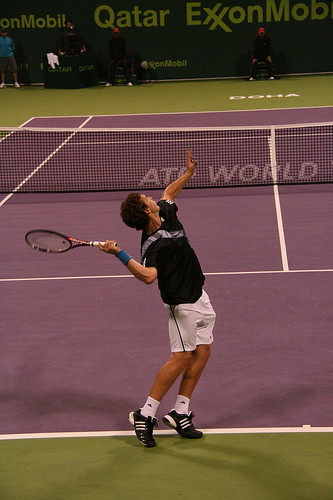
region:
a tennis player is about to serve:
[30, 154, 261, 408]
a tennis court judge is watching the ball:
[244, 24, 283, 86]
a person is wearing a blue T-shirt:
[0, 19, 32, 88]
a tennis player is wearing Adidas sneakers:
[127, 401, 204, 452]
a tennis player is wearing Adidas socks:
[124, 385, 205, 414]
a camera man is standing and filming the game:
[57, 17, 86, 65]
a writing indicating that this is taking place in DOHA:
[218, 91, 316, 106]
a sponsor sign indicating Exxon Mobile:
[180, 0, 332, 36]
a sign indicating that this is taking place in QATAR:
[42, 66, 85, 79]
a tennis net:
[2, 121, 331, 192]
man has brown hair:
[120, 195, 152, 232]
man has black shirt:
[122, 221, 198, 306]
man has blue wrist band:
[110, 246, 139, 275]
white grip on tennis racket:
[75, 233, 116, 264]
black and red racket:
[20, 224, 88, 252]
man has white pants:
[158, 304, 211, 340]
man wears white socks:
[120, 388, 180, 425]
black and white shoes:
[120, 404, 169, 463]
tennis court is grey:
[61, 188, 307, 435]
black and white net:
[15, 121, 248, 194]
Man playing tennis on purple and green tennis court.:
[17, 143, 251, 449]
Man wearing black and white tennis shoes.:
[123, 405, 209, 449]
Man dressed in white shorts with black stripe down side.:
[151, 285, 216, 358]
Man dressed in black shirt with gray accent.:
[133, 197, 216, 308]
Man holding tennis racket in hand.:
[22, 223, 118, 254]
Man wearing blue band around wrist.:
[113, 244, 137, 270]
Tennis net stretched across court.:
[115, 120, 332, 192]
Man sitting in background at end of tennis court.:
[248, 24, 287, 89]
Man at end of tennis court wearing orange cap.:
[252, 25, 269, 38]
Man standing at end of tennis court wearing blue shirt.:
[1, 36, 22, 67]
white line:
[239, 418, 304, 452]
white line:
[234, 410, 286, 446]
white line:
[247, 385, 309, 483]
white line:
[228, 415, 292, 476]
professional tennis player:
[76, 157, 244, 475]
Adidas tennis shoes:
[116, 406, 161, 450]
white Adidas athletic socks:
[138, 390, 159, 422]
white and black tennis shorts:
[151, 295, 216, 345]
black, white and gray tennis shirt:
[115, 197, 205, 304]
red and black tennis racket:
[17, 223, 118, 259]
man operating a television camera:
[47, 18, 89, 61]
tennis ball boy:
[246, 28, 277, 84]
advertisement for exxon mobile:
[142, 61, 190, 73]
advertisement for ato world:
[138, 166, 320, 189]